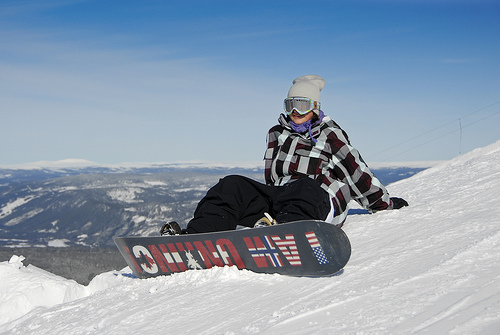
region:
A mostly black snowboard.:
[111, 221, 353, 276]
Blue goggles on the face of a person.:
[282, 96, 320, 118]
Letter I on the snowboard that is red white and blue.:
[304, 230, 329, 264]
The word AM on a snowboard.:
[241, 233, 302, 268]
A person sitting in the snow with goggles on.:
[173, 74, 409, 235]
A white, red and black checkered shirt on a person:
[263, 113, 391, 227]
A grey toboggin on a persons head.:
[286, 71, 324, 107]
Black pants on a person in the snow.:
[186, 174, 333, 231]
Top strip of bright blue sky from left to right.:
[1, 1, 498, 33]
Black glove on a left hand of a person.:
[387, 195, 408, 211]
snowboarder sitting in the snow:
[119, 78, 416, 273]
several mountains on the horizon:
[0, 159, 439, 241]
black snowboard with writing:
[110, 226, 350, 273]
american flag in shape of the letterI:
[307, 230, 329, 266]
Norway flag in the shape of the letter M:
[246, 233, 281, 270]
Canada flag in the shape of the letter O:
[133, 244, 154, 274]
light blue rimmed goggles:
[285, 97, 313, 109]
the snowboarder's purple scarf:
[285, 108, 323, 139]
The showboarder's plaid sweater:
[265, 120, 391, 215]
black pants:
[182, 174, 328, 228]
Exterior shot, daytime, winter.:
[0, 5, 496, 328]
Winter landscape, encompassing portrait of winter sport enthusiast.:
[2, 2, 495, 332]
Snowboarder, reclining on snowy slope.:
[185, 77, 402, 223]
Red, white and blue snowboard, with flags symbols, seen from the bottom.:
[85, 215, 357, 275]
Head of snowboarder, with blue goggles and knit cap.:
[271, 67, 328, 128]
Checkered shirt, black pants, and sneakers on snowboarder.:
[161, 127, 383, 227]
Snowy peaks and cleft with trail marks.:
[0, 151, 496, 331]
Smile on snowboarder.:
[290, 110, 313, 125]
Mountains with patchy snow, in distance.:
[5, 162, 405, 254]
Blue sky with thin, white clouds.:
[20, 25, 260, 150]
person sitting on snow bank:
[0, 74, 497, 334]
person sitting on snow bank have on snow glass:
[276, 95, 318, 115]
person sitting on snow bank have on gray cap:
[284, 72, 326, 100]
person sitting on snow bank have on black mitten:
[375, 196, 412, 207]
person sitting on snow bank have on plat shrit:
[264, 110, 393, 228]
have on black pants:
[180, 173, 329, 233]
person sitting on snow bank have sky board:
[111, 220, 351, 277]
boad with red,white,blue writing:
[134, 229, 331, 279]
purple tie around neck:
[280, 107, 331, 137]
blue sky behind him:
[0, 2, 499, 168]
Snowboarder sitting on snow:
[113, 71, 403, 282]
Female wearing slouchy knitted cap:
[275, 70, 334, 125]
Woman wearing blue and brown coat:
[257, 73, 384, 209]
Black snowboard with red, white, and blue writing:
[121, 220, 345, 277]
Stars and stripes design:
[305, 233, 327, 267]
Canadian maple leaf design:
[135, 248, 155, 271]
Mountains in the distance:
[2, 162, 196, 221]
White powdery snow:
[408, 154, 497, 330]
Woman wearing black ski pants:
[180, 75, 330, 233]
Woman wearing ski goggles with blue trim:
[282, 74, 324, 125]